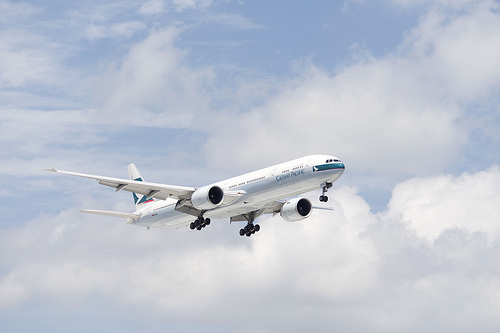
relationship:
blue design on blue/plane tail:
[129, 178, 151, 202] [124, 162, 156, 210]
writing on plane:
[271, 169, 308, 183] [42, 151, 345, 235]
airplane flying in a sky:
[40, 153, 345, 239] [2, 1, 497, 324]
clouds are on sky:
[0, 8, 499, 330] [2, 1, 497, 324]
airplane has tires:
[40, 153, 345, 239] [182, 206, 262, 236]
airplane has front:
[40, 153, 345, 239] [312, 159, 349, 179]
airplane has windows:
[40, 153, 345, 239] [312, 156, 354, 170]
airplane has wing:
[40, 153, 345, 239] [304, 201, 334, 215]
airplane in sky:
[37, 144, 353, 247] [2, 1, 497, 324]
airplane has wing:
[40, 153, 345, 239] [39, 161, 199, 197]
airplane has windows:
[40, 153, 345, 239] [321, 155, 344, 164]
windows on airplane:
[222, 170, 267, 190] [40, 153, 345, 239]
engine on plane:
[182, 181, 227, 215] [37, 150, 351, 242]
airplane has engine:
[40, 153, 345, 239] [275, 192, 315, 226]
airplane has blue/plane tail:
[40, 153, 345, 239] [124, 162, 156, 210]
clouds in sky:
[0, 0, 219, 178] [2, 1, 497, 324]